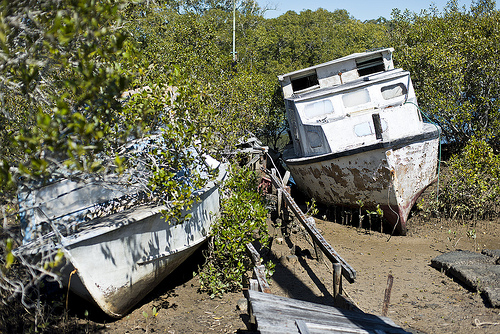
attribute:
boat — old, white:
[12, 137, 232, 319]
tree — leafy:
[0, 2, 148, 329]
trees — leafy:
[168, 16, 237, 113]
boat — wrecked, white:
[257, 25, 456, 242]